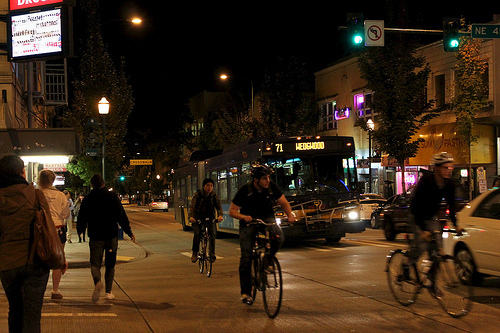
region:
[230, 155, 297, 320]
THE MAN IS RIDING HIS BIKE ON THE STREET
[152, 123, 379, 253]
THE BUS ON THE STREET IS BLACK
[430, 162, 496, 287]
THE CAR ON THE STREET IS WHITE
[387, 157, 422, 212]
THE LIGHT IS PINK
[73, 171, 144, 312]
THE WOMAN IS WALKING ACROSS THE STREET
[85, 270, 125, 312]
THE WOMAN IS WEARING WHITE SHOES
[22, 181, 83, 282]
THE WOMAN IS CARRYING A BROWN LEATHER BAG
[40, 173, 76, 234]
THE WOMAN IS WEARING A WHITE SHIRT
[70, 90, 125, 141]
THE STREET LIGHT IS BRIGHT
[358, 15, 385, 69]
THE SIGN IS NEXT TO THE TRAFFIC LIGHT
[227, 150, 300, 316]
THIS MAN IS RIDING A BIKE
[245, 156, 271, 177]
THIS HELMET IS BLACK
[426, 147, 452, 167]
THIS HELMET IS SILVER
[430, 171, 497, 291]
THE CAR IS WHITE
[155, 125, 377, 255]
THE BUS IS BIG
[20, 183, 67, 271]
THE WOMAN IS CARRYING A BROWN PURSE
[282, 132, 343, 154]
THE SIGN IS DIGITAL AND IT SAYS WEDGWOOD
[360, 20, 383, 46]
THE SIGN SAYS NO LEFT TURN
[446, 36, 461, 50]
THIS LIGHT IS GREEN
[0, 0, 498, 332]
A night time street scene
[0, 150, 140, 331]
These people are crossing the street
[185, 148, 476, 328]
Three men are riding bicycles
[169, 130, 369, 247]
A bus is on the street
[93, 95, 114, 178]
A lamp post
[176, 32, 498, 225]
Buildings are along the street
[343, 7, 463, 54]
Traffic lights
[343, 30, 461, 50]
The lights are green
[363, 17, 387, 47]
A street sign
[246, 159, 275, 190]
This man is wearing a helmet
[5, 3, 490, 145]
A black sky at night.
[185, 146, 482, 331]
People riding bicycles down the street.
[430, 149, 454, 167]
A white bicycle helmet.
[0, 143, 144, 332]
People walking across the street.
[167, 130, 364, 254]
A large dark colored bus.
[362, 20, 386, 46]
A red, white, and black "Do not turn left" sign.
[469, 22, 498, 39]
A green and white street sign.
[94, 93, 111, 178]
A street light.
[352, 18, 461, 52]
Traffic lights.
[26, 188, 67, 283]
A brown shoulder bag.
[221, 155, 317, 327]
man riding a bike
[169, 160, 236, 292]
man riding a bike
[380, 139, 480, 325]
man riding a bike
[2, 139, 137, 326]
people crossing the street